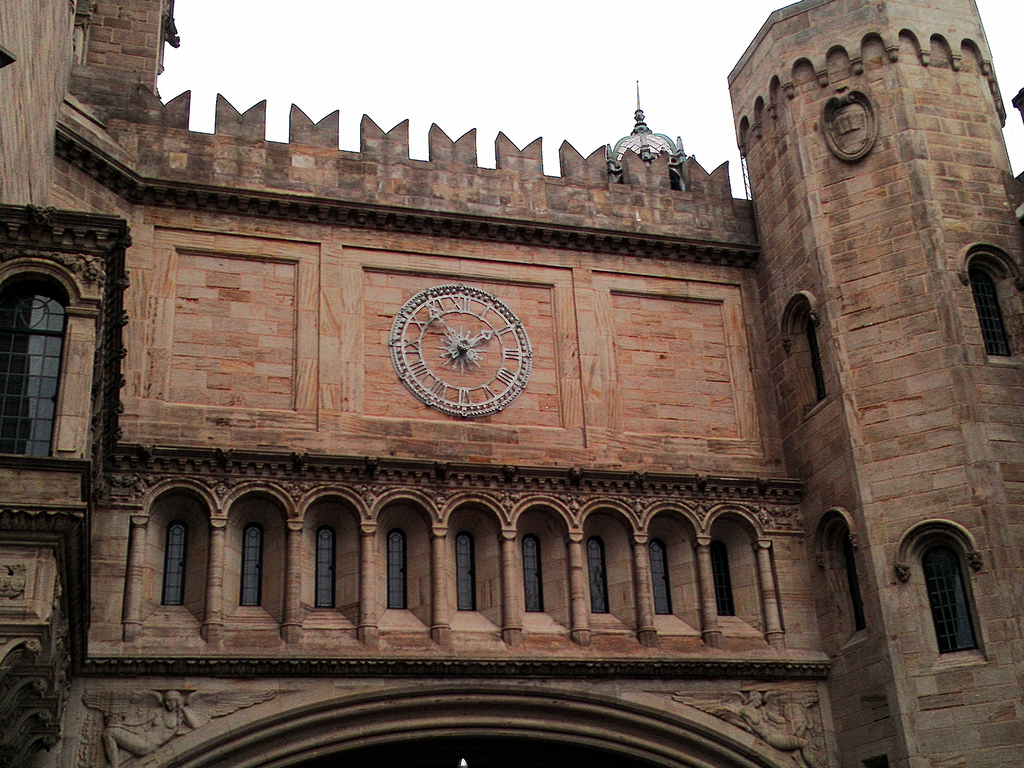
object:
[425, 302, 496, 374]
angel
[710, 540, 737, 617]
window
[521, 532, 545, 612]
window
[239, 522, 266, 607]
window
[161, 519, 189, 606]
window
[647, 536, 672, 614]
window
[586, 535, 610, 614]
window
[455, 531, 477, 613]
window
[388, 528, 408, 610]
window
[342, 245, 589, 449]
design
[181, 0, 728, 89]
sky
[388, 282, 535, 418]
clock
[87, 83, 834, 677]
wall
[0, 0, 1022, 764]
building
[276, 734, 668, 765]
entranceway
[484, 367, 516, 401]
roman numeralas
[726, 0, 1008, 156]
top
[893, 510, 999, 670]
window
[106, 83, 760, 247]
brick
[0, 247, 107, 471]
window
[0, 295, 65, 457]
dividers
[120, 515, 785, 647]
pillars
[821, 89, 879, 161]
crest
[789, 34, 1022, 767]
wall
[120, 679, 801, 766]
archway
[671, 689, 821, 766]
angel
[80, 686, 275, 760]
angel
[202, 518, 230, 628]
pillars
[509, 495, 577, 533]
arches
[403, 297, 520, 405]
numerals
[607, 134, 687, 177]
roof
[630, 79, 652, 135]
spire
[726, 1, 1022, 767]
tower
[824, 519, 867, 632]
windows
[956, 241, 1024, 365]
windows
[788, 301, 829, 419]
windows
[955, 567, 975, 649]
reflection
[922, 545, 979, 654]
pane